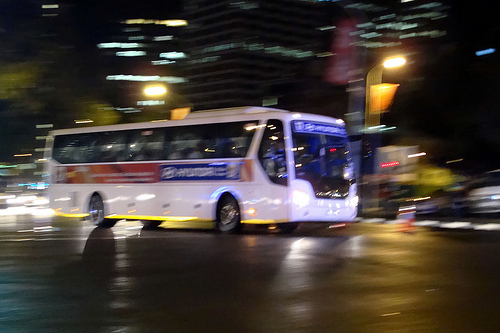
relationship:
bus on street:
[42, 105, 360, 237] [1, 215, 499, 331]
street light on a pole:
[382, 54, 407, 69] [363, 64, 379, 220]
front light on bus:
[293, 190, 309, 208] [42, 105, 360, 237]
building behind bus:
[179, 3, 345, 123] [42, 105, 360, 237]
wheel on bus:
[217, 194, 244, 234] [42, 105, 360, 237]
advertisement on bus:
[51, 160, 253, 185] [42, 105, 360, 237]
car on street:
[454, 169, 499, 217] [1, 215, 499, 331]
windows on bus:
[54, 120, 259, 165] [42, 105, 360, 237]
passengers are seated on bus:
[73, 139, 235, 163] [42, 105, 360, 237]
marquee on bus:
[293, 120, 348, 137] [42, 105, 360, 237]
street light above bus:
[382, 54, 407, 69] [42, 105, 360, 237]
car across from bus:
[454, 169, 499, 217] [42, 105, 360, 237]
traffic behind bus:
[1, 194, 53, 223] [42, 105, 360, 237]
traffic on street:
[1, 194, 53, 223] [1, 215, 499, 331]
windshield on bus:
[291, 121, 356, 200] [42, 105, 360, 237]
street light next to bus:
[382, 54, 407, 69] [42, 105, 360, 237]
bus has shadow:
[42, 105, 360, 237] [52, 228, 349, 308]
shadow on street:
[52, 228, 349, 308] [1, 215, 499, 331]